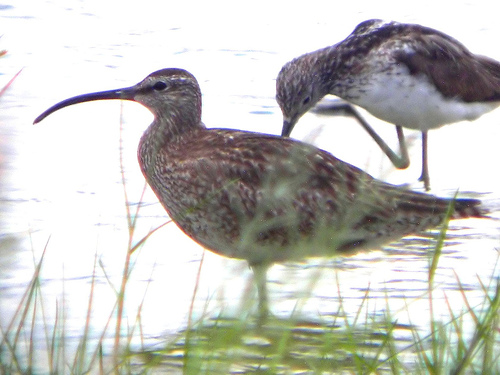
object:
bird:
[278, 19, 499, 191]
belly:
[337, 69, 483, 130]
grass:
[0, 186, 497, 374]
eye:
[152, 82, 167, 91]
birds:
[27, 67, 486, 337]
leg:
[418, 130, 430, 191]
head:
[30, 66, 202, 127]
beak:
[31, 86, 143, 123]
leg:
[253, 262, 268, 319]